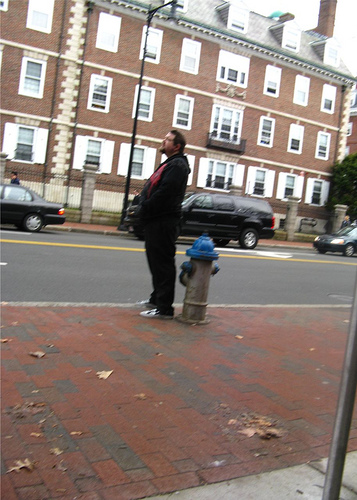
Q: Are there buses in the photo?
A: No, there are no buses.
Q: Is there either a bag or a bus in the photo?
A: No, there are no buses or bags.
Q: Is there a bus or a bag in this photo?
A: No, there are no buses or bags.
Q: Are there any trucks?
A: No, there are no trucks.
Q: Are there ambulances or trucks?
A: No, there are no trucks or ambulances.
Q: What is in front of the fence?
A: The car is in front of the fence.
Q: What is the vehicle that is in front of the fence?
A: The vehicle is a car.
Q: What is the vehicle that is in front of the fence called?
A: The vehicle is a car.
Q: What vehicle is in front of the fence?
A: The vehicle is a car.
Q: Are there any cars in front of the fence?
A: Yes, there is a car in front of the fence.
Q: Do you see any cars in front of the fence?
A: Yes, there is a car in front of the fence.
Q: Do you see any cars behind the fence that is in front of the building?
A: No, the car is in front of the fence.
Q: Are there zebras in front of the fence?
A: No, there is a car in front of the fence.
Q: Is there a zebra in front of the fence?
A: No, there is a car in front of the fence.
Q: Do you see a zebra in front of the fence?
A: No, there is a car in front of the fence.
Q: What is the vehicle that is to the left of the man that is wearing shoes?
A: The vehicle is a car.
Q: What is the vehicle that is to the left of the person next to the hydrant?
A: The vehicle is a car.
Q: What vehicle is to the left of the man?
A: The vehicle is a car.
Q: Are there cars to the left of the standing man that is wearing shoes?
A: Yes, there is a car to the left of the man.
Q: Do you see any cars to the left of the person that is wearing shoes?
A: Yes, there is a car to the left of the man.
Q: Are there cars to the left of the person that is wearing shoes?
A: Yes, there is a car to the left of the man.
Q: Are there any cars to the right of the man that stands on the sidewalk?
A: No, the car is to the left of the man.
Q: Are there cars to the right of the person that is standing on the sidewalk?
A: No, the car is to the left of the man.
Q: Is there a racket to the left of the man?
A: No, there is a car to the left of the man.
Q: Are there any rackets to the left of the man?
A: No, there is a car to the left of the man.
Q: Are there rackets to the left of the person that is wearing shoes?
A: No, there is a car to the left of the man.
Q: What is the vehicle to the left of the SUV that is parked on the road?
A: The vehicle is a car.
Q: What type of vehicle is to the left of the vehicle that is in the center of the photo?
A: The vehicle is a car.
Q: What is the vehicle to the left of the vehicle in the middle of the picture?
A: The vehicle is a car.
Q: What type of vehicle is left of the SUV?
A: The vehicle is a car.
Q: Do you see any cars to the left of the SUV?
A: Yes, there is a car to the left of the SUV.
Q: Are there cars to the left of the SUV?
A: Yes, there is a car to the left of the SUV.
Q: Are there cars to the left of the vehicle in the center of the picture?
A: Yes, there is a car to the left of the SUV.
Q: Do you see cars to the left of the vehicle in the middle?
A: Yes, there is a car to the left of the SUV.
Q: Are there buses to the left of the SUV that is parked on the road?
A: No, there is a car to the left of the SUV.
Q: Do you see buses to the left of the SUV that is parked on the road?
A: No, there is a car to the left of the SUV.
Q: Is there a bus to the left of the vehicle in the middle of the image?
A: No, there is a car to the left of the SUV.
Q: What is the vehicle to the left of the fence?
A: The vehicle is a car.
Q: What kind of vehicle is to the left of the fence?
A: The vehicle is a car.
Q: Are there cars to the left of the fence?
A: Yes, there is a car to the left of the fence.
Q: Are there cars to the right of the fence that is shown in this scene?
A: No, the car is to the left of the fence.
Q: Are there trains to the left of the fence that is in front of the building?
A: No, there is a car to the left of the fence.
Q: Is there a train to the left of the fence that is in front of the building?
A: No, there is a car to the left of the fence.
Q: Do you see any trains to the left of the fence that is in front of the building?
A: No, there is a car to the left of the fence.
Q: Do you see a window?
A: Yes, there is a window.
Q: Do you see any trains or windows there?
A: Yes, there is a window.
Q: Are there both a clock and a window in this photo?
A: No, there is a window but no clocks.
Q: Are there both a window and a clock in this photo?
A: No, there is a window but no clocks.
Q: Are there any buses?
A: No, there are no buses.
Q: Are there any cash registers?
A: No, there are no cash registers.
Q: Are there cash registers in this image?
A: No, there are no cash registers.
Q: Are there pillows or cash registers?
A: No, there are no cash registers or pillows.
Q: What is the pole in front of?
A: The pole is in front of the side walk.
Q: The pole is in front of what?
A: The pole is in front of the side walk.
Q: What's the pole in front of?
A: The pole is in front of the side walk.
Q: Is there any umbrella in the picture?
A: No, there are no umbrellas.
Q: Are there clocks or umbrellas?
A: No, there are no umbrellas or clocks.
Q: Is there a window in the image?
A: Yes, there is a window.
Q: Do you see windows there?
A: Yes, there is a window.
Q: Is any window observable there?
A: Yes, there is a window.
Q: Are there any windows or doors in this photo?
A: Yes, there is a window.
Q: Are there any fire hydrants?
A: Yes, there is a fire hydrant.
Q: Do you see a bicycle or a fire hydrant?
A: Yes, there is a fire hydrant.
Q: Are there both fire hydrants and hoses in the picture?
A: No, there is a fire hydrant but no hoses.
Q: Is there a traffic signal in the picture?
A: No, there are no traffic lights.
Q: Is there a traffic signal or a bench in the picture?
A: No, there are no traffic lights or benches.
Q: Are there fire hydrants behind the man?
A: Yes, there is a fire hydrant behind the man.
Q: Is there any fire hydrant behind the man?
A: Yes, there is a fire hydrant behind the man.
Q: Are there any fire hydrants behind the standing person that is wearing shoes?
A: Yes, there is a fire hydrant behind the man.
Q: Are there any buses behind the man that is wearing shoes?
A: No, there is a fire hydrant behind the man.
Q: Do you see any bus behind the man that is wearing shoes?
A: No, there is a fire hydrant behind the man.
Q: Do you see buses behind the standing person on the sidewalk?
A: No, there is a fire hydrant behind the man.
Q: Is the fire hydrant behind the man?
A: Yes, the fire hydrant is behind the man.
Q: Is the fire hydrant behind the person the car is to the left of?
A: Yes, the fire hydrant is behind the man.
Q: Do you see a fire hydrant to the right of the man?
A: Yes, there is a fire hydrant to the right of the man.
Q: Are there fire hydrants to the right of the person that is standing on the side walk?
A: Yes, there is a fire hydrant to the right of the man.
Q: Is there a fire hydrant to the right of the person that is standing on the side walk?
A: Yes, there is a fire hydrant to the right of the man.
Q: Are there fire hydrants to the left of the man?
A: No, the fire hydrant is to the right of the man.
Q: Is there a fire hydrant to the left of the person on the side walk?
A: No, the fire hydrant is to the right of the man.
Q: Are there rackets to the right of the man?
A: No, there is a fire hydrant to the right of the man.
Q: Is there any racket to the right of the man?
A: No, there is a fire hydrant to the right of the man.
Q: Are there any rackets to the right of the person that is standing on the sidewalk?
A: No, there is a fire hydrant to the right of the man.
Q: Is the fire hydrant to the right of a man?
A: Yes, the fire hydrant is to the right of a man.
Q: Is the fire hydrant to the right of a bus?
A: No, the fire hydrant is to the right of a man.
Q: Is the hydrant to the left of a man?
A: No, the hydrant is to the right of a man.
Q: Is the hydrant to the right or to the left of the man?
A: The hydrant is to the right of the man.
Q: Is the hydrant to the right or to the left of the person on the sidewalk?
A: The hydrant is to the right of the man.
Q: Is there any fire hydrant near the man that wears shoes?
A: Yes, there is a fire hydrant near the man.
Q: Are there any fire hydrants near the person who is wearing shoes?
A: Yes, there is a fire hydrant near the man.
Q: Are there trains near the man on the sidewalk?
A: No, there is a fire hydrant near the man.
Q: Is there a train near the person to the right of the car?
A: No, there is a fire hydrant near the man.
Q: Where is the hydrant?
A: The hydrant is on the sidewalk.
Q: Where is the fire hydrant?
A: The hydrant is on the sidewalk.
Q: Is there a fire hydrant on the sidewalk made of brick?
A: Yes, there is a fire hydrant on the side walk.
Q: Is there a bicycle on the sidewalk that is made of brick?
A: No, there is a fire hydrant on the sidewalk.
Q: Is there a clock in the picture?
A: No, there are no clocks.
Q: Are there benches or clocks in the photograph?
A: No, there are no clocks or benches.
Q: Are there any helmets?
A: No, there are no helmets.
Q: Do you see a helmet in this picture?
A: No, there are no helmets.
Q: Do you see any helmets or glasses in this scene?
A: No, there are no helmets or glasses.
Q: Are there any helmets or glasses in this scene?
A: No, there are no helmets or glasses.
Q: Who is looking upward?
A: The man is looking upward.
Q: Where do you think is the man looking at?
A: The man is looking upward.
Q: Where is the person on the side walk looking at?
A: The man is looking upward.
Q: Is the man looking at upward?
A: Yes, the man is looking upward.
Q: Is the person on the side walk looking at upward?
A: Yes, the man is looking upward.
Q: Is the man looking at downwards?
A: No, the man is looking upward.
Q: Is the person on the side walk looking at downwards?
A: No, the man is looking upward.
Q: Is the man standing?
A: Yes, the man is standing.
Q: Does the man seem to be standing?
A: Yes, the man is standing.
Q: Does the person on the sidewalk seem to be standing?
A: Yes, the man is standing.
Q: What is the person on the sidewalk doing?
A: The man is standing.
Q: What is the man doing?
A: The man is standing.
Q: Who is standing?
A: The man is standing.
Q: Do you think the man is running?
A: No, the man is standing.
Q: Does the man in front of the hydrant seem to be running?
A: No, the man is standing.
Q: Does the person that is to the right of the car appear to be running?
A: No, the man is standing.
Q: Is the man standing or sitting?
A: The man is standing.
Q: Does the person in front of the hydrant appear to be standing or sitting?
A: The man is standing.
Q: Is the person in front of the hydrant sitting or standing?
A: The man is standing.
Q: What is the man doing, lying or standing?
A: The man is standing.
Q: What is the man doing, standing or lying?
A: The man is standing.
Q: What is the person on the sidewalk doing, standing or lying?
A: The man is standing.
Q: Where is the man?
A: The man is on the sidewalk.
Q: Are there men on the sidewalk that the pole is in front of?
A: Yes, there is a man on the side walk.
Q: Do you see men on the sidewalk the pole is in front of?
A: Yes, there is a man on the side walk.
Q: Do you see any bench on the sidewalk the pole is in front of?
A: No, there is a man on the sidewalk.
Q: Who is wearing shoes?
A: The man is wearing shoes.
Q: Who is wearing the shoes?
A: The man is wearing shoes.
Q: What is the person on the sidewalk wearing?
A: The man is wearing shoes.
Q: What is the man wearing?
A: The man is wearing shoes.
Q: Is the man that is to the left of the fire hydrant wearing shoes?
A: Yes, the man is wearing shoes.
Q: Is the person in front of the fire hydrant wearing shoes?
A: Yes, the man is wearing shoes.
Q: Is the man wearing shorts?
A: No, the man is wearing shoes.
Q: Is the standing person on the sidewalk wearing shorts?
A: No, the man is wearing shoes.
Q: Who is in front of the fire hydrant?
A: The man is in front of the fire hydrant.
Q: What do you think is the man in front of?
A: The man is in front of the hydrant.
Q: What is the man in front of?
A: The man is in front of the hydrant.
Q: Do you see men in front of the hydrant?
A: Yes, there is a man in front of the hydrant.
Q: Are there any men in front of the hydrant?
A: Yes, there is a man in front of the hydrant.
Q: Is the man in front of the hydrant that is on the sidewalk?
A: Yes, the man is in front of the fire hydrant.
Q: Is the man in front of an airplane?
A: No, the man is in front of the fire hydrant.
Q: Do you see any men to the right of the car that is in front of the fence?
A: Yes, there is a man to the right of the car.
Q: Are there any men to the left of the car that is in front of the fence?
A: No, the man is to the right of the car.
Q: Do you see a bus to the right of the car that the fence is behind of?
A: No, there is a man to the right of the car.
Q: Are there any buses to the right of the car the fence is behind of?
A: No, there is a man to the right of the car.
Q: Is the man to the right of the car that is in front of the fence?
A: Yes, the man is to the right of the car.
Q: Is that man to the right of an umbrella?
A: No, the man is to the right of the car.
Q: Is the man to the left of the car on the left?
A: No, the man is to the right of the car.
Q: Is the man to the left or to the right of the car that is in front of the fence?
A: The man is to the right of the car.